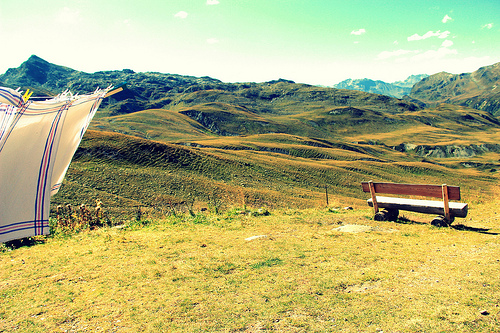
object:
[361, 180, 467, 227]
bench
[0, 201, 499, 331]
field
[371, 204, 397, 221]
wheels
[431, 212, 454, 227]
wheels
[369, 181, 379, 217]
stick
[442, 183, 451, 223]
stick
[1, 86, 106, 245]
blanket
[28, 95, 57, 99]
string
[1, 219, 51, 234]
stripes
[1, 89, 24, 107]
stripes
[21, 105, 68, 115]
stripes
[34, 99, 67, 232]
stripes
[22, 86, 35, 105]
clothespin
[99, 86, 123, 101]
clothespin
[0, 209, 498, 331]
grass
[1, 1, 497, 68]
sky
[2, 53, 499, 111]
mountains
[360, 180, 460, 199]
back rest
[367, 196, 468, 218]
seat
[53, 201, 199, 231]
fence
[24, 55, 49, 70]
peak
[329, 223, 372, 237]
spot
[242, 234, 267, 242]
spot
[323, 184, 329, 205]
fence post